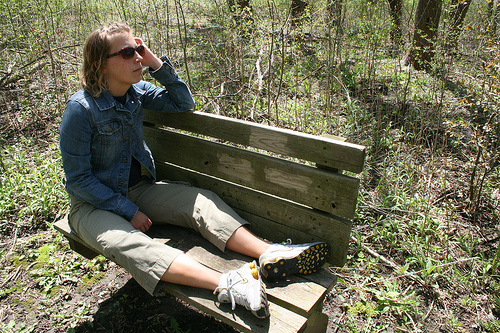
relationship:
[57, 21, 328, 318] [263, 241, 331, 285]
person has a shoe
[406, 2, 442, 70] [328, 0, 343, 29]
tree has a trunk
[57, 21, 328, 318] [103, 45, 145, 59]
person has on sunglasses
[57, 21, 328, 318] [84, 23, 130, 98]
person has hair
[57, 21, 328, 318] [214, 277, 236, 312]
person has shoelaces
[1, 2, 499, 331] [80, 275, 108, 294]
ground has dirt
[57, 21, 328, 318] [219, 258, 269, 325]
person has a foot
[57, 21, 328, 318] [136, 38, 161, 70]
person has hand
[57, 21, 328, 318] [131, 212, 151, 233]
person has a hand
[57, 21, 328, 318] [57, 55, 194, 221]
person has a jacket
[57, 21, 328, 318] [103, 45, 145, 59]
person wearing sunglasses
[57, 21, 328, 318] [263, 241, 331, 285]
person has on shoe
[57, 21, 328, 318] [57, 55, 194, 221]
person has on a jacket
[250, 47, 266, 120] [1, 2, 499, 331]
branches are on ground